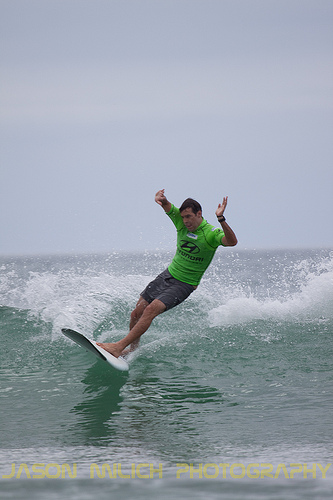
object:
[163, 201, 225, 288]
shirt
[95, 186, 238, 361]
man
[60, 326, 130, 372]
board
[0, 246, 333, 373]
wave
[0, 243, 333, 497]
water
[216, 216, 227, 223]
watch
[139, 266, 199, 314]
shorts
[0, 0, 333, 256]
sky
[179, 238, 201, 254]
logo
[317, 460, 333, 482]
letters